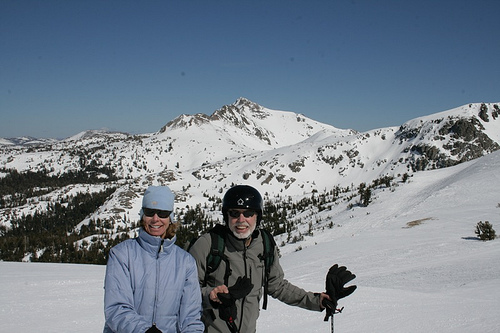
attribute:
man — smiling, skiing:
[191, 183, 327, 332]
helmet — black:
[223, 184, 264, 219]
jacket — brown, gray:
[186, 226, 320, 332]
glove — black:
[323, 263, 355, 322]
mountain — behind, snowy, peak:
[149, 95, 335, 162]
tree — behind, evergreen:
[275, 212, 287, 232]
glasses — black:
[227, 209, 256, 218]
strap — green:
[202, 222, 224, 278]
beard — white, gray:
[225, 222, 260, 238]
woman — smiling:
[104, 184, 205, 332]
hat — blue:
[143, 185, 177, 215]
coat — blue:
[102, 224, 208, 332]